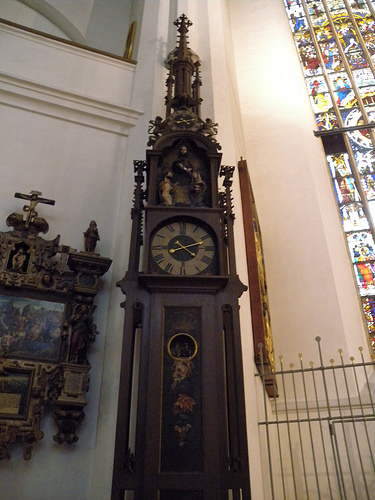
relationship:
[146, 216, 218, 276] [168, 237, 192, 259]
clock on hand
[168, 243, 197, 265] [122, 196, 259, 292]
hand on clock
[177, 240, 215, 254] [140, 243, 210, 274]
mark on numbers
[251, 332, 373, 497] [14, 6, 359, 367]
bar in church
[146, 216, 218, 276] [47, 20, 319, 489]
clock in church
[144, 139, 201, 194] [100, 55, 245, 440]
ornament in clock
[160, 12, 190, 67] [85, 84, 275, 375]
cross on clock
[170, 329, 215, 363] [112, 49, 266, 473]
circle on clock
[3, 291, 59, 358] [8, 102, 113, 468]
portrait on wall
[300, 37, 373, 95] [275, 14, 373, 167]
bars on window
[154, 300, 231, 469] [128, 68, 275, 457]
design on clock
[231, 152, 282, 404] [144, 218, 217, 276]
picture on left side of clock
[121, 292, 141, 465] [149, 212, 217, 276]
slot on side of clock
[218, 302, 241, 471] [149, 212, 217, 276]
slot on side of clock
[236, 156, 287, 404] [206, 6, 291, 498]
picture on wall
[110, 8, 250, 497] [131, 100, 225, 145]
clock embellished with images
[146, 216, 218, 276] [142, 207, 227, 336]
clock of clock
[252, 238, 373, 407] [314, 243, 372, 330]
stained glass window panel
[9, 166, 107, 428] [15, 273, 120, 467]
religious artwork hanging on wall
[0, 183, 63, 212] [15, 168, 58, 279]
cross showing jesus on cross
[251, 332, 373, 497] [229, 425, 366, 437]
bar a metal gate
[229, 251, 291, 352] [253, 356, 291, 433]
artwork hanging from wall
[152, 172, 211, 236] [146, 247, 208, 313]
religious images on clock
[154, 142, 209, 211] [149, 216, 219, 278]
religious figurines above clock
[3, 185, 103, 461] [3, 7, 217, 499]
religions painting on wall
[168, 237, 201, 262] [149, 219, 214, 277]
hand of a clock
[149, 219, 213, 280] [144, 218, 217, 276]
roman numerals on a clock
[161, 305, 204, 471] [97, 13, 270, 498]
religious drawings on front of a clock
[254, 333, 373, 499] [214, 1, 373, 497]
decoration against a wall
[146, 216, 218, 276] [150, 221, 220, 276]
clock with roman numerals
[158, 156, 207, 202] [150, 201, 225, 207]
statues in shelf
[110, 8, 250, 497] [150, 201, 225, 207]
clock has shelf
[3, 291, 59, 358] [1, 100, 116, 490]
portrait hanging on wall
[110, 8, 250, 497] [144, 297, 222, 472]
clock has front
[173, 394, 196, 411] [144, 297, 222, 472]
leaves on front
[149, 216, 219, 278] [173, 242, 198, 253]
clock has hand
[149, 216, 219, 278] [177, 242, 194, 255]
clock has hand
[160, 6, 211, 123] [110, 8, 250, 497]
steeple on top of clock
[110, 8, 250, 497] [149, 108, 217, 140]
clock with ornaments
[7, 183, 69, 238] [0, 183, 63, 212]
cross with cross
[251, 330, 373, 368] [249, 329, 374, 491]
balls on bar